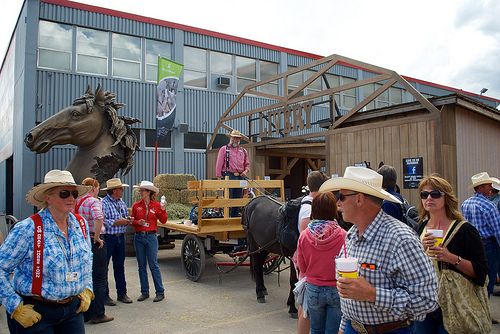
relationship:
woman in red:
[127, 179, 178, 286] [137, 195, 173, 224]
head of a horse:
[25, 79, 140, 182] [21, 87, 144, 188]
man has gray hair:
[214, 130, 250, 218] [228, 137, 243, 150]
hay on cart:
[156, 161, 209, 231] [131, 173, 285, 282]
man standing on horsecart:
[214, 130, 250, 218] [152, 174, 309, 319]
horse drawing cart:
[240, 193, 309, 319] [152, 172, 284, 282]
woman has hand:
[412, 171, 487, 325] [427, 241, 454, 264]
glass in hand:
[424, 225, 447, 256] [427, 241, 454, 264]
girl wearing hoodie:
[291, 191, 349, 333] [297, 221, 342, 276]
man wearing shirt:
[0, 169, 96, 333] [0, 207, 92, 316]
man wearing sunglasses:
[0, 169, 96, 333] [48, 187, 79, 201]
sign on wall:
[399, 152, 433, 187] [322, 128, 499, 212]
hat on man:
[316, 165, 403, 205] [317, 165, 440, 333]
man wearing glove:
[0, 164, 110, 332] [75, 285, 93, 315]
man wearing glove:
[0, 164, 110, 332] [10, 300, 46, 330]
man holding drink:
[315, 170, 477, 331] [318, 234, 416, 301]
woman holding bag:
[412, 171, 488, 333] [438, 220, 493, 332]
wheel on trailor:
[180, 233, 207, 280] [156, 176, 284, 239]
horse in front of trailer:
[240, 193, 306, 318] [152, 175, 285, 280]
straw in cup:
[341, 236, 346, 256] [334, 255, 361, 300]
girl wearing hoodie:
[294, 191, 349, 332] [297, 218, 349, 285]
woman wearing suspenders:
[127, 179, 178, 286] [136, 202, 156, 234]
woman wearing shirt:
[127, 179, 178, 286] [131, 194, 160, 234]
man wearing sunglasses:
[317, 165, 440, 333] [335, 189, 358, 200]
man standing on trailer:
[212, 124, 257, 223] [154, 69, 302, 257]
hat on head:
[317, 165, 403, 205] [335, 189, 381, 223]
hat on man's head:
[225, 129, 245, 140] [224, 122, 242, 141]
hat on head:
[102, 171, 134, 186] [106, 186, 124, 199]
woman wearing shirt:
[127, 182, 169, 304] [128, 198, 168, 235]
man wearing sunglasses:
[0, 169, 96, 333] [50, 188, 80, 208]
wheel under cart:
[180, 233, 207, 282] [134, 166, 290, 249]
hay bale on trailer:
[132, 174, 221, 221] [136, 179, 292, 281]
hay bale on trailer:
[174, 185, 201, 210] [136, 179, 292, 281]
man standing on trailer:
[214, 130, 250, 218] [153, 173, 291, 252]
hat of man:
[227, 130, 247, 137] [214, 130, 250, 218]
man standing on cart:
[214, 130, 250, 218] [131, 173, 285, 282]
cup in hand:
[333, 252, 361, 282] [336, 272, 376, 305]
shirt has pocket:
[331, 205, 440, 317] [355, 271, 378, 283]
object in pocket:
[358, 259, 377, 270] [355, 271, 378, 283]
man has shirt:
[317, 165, 440, 333] [331, 205, 440, 317]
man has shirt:
[317, 165, 440, 333] [330, 207, 452, 320]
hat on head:
[316, 165, 403, 205] [335, 184, 383, 225]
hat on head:
[465, 168, 499, 193] [473, 175, 493, 196]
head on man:
[138, 185, 152, 198] [127, 177, 170, 302]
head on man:
[106, 183, 124, 199] [96, 175, 136, 305]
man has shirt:
[214, 130, 250, 218] [213, 144, 248, 176]